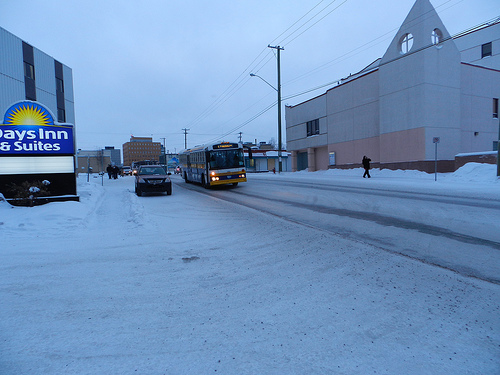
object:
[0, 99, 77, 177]
sign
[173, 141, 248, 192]
bus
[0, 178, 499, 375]
road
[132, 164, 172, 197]
suv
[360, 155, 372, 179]
person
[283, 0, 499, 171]
building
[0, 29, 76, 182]
hotel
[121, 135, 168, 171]
building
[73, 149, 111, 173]
building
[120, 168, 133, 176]
vehicle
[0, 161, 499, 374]
snow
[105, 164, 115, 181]
people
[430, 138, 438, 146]
sign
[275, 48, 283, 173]
pole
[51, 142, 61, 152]
writing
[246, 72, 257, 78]
light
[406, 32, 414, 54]
window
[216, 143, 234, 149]
word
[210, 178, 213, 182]
lights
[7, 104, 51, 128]
sun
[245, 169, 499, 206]
sidewalk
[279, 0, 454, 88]
wires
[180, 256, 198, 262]
mark